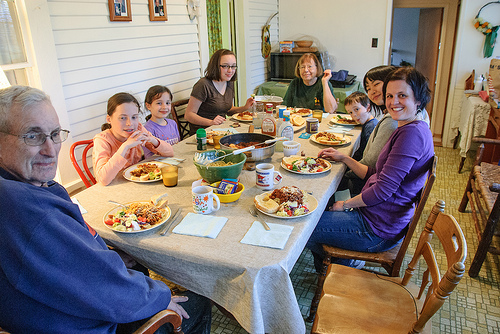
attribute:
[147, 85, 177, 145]
girl — little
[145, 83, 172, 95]
hair — brown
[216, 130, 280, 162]
bowl — silver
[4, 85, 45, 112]
hair — gray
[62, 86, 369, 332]
table — long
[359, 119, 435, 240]
top — purple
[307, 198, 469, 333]
chair — browm, empty, wooden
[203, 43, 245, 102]
woman — smiling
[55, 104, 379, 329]
tablecloth — white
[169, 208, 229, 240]
napkins — white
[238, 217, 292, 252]
napkins — white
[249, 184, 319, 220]
plate — full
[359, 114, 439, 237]
shirt — purple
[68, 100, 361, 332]
tablecloth — grey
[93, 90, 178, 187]
girl — little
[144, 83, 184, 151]
girl — little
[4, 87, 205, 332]
man — old